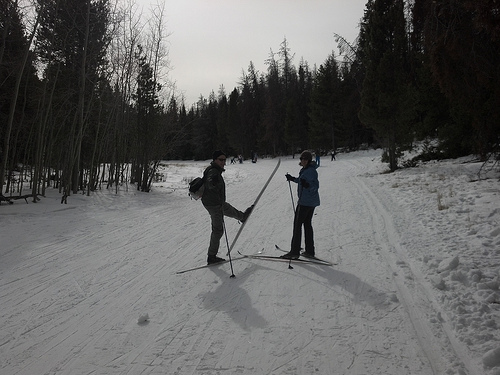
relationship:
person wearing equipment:
[201, 150, 253, 265] [175, 159, 281, 278]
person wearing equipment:
[280, 151, 319, 259] [238, 173, 336, 266]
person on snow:
[201, 150, 253, 265] [0, 137, 499, 374]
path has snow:
[1, 161, 487, 374] [0, 137, 499, 374]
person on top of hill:
[201, 150, 253, 265] [1, 124, 499, 374]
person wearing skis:
[201, 150, 253, 265] [175, 159, 281, 278]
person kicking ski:
[201, 150, 253, 265] [226, 157, 281, 256]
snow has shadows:
[0, 137, 499, 374] [207, 261, 386, 329]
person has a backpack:
[201, 150, 253, 265] [188, 177, 206, 201]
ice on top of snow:
[137, 311, 147, 324] [0, 137, 499, 374]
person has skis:
[201, 150, 253, 265] [175, 159, 281, 278]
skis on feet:
[175, 159, 281, 278] [207, 205, 254, 264]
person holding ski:
[201, 150, 253, 265] [226, 157, 281, 256]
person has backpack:
[201, 150, 253, 265] [188, 177, 206, 201]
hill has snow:
[1, 124, 499, 374] [0, 137, 499, 374]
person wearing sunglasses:
[201, 150, 253, 265] [217, 157, 227, 162]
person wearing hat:
[280, 151, 319, 259] [299, 150, 313, 162]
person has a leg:
[201, 150, 253, 265] [207, 208, 225, 261]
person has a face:
[201, 150, 253, 265] [214, 155, 226, 170]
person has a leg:
[280, 151, 319, 259] [282, 205, 311, 258]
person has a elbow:
[201, 150, 253, 265] [206, 184, 216, 193]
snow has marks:
[0, 137, 499, 374] [0, 160, 488, 374]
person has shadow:
[201, 150, 253, 265] [203, 264, 327, 330]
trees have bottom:
[0, 0, 500, 203] [0, 133, 500, 205]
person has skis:
[280, 151, 319, 259] [237, 244, 336, 267]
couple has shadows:
[201, 151, 320, 264] [207, 261, 386, 329]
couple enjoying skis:
[201, 151, 320, 264] [175, 159, 281, 278]